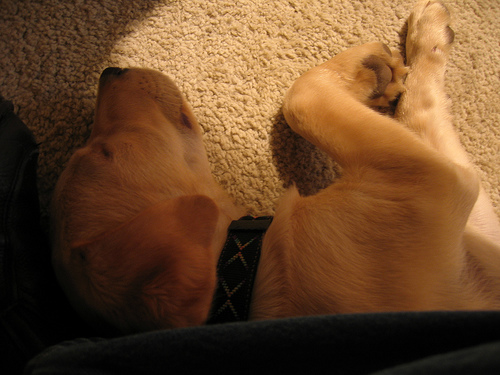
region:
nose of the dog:
[90, 42, 151, 89]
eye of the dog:
[80, 127, 135, 167]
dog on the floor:
[47, 37, 463, 302]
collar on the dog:
[191, 177, 291, 332]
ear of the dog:
[50, 148, 240, 314]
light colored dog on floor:
[58, 25, 492, 287]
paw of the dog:
[337, 38, 414, 111]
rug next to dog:
[191, 18, 272, 83]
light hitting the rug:
[219, 25, 298, 89]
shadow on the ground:
[78, 10, 170, 53]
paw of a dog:
[326, 33, 412, 110]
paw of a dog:
[395, 1, 462, 68]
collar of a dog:
[189, 203, 284, 338]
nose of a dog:
[91, 62, 127, 96]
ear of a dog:
[62, 180, 221, 335]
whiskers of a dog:
[121, 63, 201, 129]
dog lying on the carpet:
[39, 0, 499, 348]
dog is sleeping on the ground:
[37, 2, 499, 324]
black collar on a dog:
[190, 197, 281, 344]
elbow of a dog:
[429, 159, 486, 216]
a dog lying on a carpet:
[20, 6, 499, 331]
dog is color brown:
[39, 4, 496, 339]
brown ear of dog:
[76, 191, 217, 329]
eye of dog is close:
[78, 122, 120, 169]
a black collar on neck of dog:
[206, 199, 276, 324]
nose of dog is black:
[93, 54, 132, 88]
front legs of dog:
[270, 4, 491, 199]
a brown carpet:
[6, 0, 493, 94]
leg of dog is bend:
[258, 45, 490, 253]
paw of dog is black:
[346, 28, 418, 106]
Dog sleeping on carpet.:
[1, 0, 478, 372]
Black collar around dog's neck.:
[204, 211, 274, 325]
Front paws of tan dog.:
[270, 0, 495, 204]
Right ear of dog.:
[73, 193, 225, 328]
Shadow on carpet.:
[4, 0, 175, 93]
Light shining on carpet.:
[133, 0, 355, 85]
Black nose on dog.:
[96, 62, 126, 82]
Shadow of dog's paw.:
[267, 89, 343, 199]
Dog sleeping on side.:
[17, 0, 495, 352]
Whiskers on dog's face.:
[137, 67, 194, 123]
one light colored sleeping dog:
[28, 2, 494, 321]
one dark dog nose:
[93, 61, 131, 88]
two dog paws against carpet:
[275, 5, 475, 140]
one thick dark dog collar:
[201, 208, 280, 326]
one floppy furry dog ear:
[73, 186, 224, 327]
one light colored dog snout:
[133, 63, 196, 140]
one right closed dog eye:
[91, 135, 117, 166]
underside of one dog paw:
[360, 40, 412, 104]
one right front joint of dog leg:
[408, 140, 483, 237]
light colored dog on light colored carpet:
[16, 3, 496, 268]